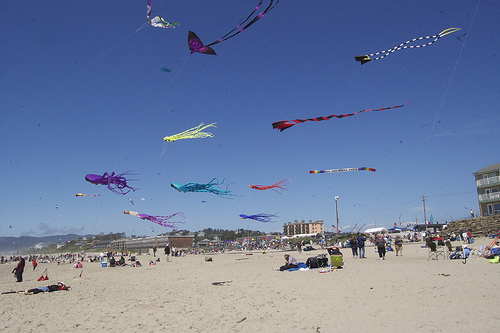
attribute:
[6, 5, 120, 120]
sky — clear, blue, part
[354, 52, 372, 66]
kite — white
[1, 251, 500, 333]
sand — section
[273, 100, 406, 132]
kite — red, long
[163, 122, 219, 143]
kite — yellow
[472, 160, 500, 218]
house — blue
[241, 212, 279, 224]
kite — purple, black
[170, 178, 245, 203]
kite — blue, black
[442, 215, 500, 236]
wall — brown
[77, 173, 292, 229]
kites — colorful, flown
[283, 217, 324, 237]
building — part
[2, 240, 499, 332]
beach — part